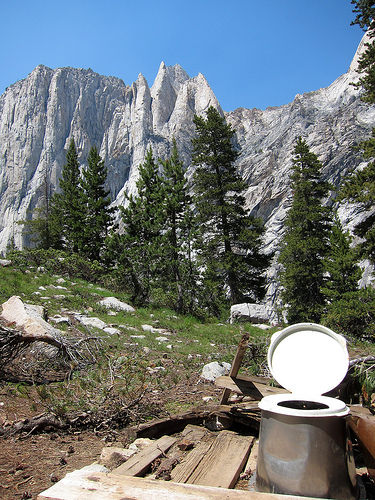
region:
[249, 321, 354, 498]
Silver metal toilet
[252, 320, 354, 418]
White toilet seat and cover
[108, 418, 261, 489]
Planks of light wood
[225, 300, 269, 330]
Large light gray boulder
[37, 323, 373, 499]
Pile of trash in nature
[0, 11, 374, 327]
Tall mountain range and cliffs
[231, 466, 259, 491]
Water on a piece of wood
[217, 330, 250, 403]
Wood piece sticking from the ground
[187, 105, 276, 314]
tall green pine tree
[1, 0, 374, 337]
Mountain scenery with pine trees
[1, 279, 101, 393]
pile of rocks on ground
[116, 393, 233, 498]
boards of wood on ground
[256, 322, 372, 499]
silver pot on wood boards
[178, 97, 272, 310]
tall tree in front of mountail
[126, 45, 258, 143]
snowy mountain peek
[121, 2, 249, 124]
clear blue sky behind mountains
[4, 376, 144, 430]
pile of sticks on ground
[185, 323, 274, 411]
rock behind wood pieces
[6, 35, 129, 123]
flat mountain top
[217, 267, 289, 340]
white rock in front of trees on ground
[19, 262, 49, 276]
Small white rocks on the ground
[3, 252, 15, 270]
Small white rocks on the ground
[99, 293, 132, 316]
Small white rocks on the ground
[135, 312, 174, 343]
Small white rocks on the ground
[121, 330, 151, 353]
Small white rocks on the ground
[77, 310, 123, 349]
Small white rocks on the ground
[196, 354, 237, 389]
Small white rocks on the ground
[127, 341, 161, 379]
Small white rocks on the ground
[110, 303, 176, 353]
Small white rocks on the ground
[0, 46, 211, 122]
tips of large mountains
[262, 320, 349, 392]
top cover of toilet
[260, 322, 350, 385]
cover of toilet seat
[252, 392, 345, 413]
white toilet seat top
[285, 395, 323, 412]
black bowl inside toilet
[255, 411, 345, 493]
silver base of toilet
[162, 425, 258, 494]
brown wooden planks on ground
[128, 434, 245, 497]
wooden platform for toilet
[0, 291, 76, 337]
large white rocks on side of hill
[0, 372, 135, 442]
dead tree branches on ground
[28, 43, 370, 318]
a clear view of mountains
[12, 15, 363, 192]
a beautiful view of mountains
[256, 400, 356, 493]
a iron box toilet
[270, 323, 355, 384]
a top part of toilet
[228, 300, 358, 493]
a toilet shaped box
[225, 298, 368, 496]
a toilet shaped tin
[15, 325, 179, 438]
a dust trees near by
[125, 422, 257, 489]
steps made with wood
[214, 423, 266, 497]
gap in the wood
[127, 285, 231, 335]
green grass on earth